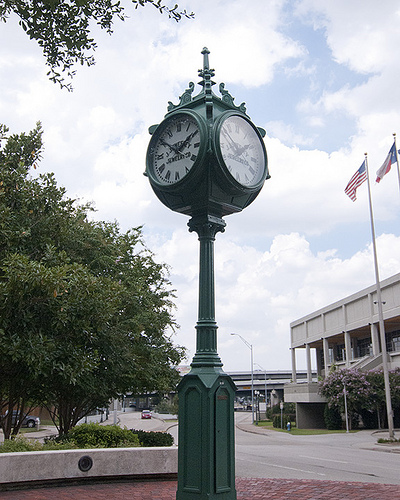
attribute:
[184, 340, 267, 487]
pole — green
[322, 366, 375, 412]
leaves — pink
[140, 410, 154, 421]
car — red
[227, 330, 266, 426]
street light — tall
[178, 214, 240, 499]
pole — green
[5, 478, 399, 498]
ground — brick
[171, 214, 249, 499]
clock pillar — metallic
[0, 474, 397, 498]
floor — brick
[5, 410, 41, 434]
car — gray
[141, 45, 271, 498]
pole — metal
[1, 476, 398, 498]
sidewalk — brick, red, brown